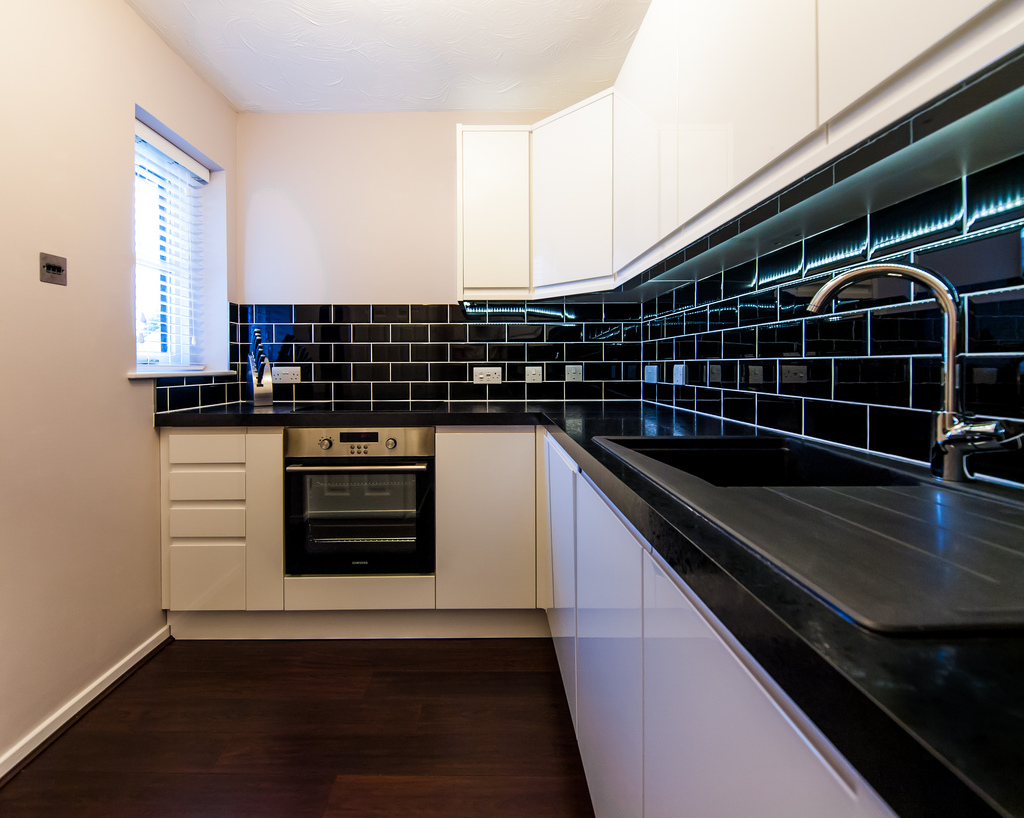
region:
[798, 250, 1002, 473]
Silver colored faucet on the sink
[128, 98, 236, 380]
Window in the wall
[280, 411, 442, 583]
Oven in the room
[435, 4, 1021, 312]
White upper cabinets in the room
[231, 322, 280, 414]
Knife rack on the counter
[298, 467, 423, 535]
Glass door on the oven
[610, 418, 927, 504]
sink in the room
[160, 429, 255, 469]
drawer in the cabinet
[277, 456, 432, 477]
Handle on the door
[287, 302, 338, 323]
Small dark tile on the wall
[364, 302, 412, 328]
Small dark tile on the wall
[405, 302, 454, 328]
Small dark tile on the wall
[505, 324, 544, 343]
Small dark tile on the wall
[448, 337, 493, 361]
Small dark tile on the wall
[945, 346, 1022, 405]
Small dark tile on the wall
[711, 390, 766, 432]
Small dark tile on the wall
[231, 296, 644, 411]
shiny black tiles on wall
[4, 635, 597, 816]
dark stained hardwood floor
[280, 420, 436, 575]
stainless steel and glass oven built into cabinets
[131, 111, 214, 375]
window with shades partially open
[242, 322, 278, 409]
wooden block of knives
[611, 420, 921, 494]
large opening for kitchen sink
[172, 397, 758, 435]
jet black counter top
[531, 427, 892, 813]
shiny white cabinets under counter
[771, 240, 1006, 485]
Faucet in the kitchen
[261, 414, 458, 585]
Silver stove in the kitchen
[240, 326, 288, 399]
Set of knives on counter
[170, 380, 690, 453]
The counter is shiny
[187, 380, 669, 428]
The counter is black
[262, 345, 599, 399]
Electrical outlets in the wall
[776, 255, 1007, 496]
Faucet above sink is silver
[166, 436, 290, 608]
White drawers near the stove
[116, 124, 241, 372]
Blinds in the window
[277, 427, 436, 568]
An oven in a kitchen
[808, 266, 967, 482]
A chrome faucet over a sink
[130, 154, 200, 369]
White blinds on a window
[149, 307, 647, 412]
Black tile behind a stove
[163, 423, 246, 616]
White drawers near a stove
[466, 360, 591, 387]
Electrical outlets on a wall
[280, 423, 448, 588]
silver and black oven in kitchen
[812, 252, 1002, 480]
silver faucet in kitchen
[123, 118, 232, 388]
large white window in kitchen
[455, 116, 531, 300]
white colored cabinet in kitchen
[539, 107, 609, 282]
white colored cabinet in kitchen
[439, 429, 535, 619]
white colored cabinet in kitchen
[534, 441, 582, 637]
white colored cabinet in kitchen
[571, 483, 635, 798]
white colored cabinet in kitchen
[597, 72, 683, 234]
white colored cabinet in kitchen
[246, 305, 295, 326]
black tile on wall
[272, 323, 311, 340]
black tile on wall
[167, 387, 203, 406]
black tile on wall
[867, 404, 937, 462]
black tile on wall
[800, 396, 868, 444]
black tile on wall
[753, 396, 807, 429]
black tile on wall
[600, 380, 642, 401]
black tile on wall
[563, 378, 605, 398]
black tile on wall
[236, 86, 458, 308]
a small wall that is white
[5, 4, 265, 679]
a large wall that is white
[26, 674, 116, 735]
a floor board that is white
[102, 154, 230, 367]
a window that is white